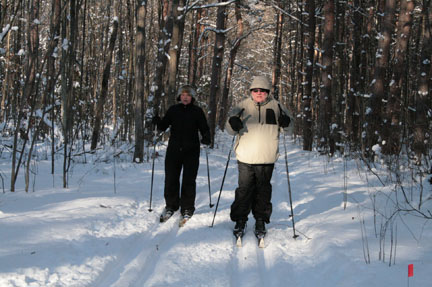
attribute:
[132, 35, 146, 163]
trunk — tall, high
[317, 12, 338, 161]
tree — tall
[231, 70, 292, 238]
person — skiing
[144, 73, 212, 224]
person — skiing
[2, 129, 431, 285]
snow — white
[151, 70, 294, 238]
people — skiing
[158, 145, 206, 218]
pants — black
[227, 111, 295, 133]
gloves — black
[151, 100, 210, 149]
jacket — black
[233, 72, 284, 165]
jacket — beige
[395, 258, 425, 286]
flag — red, small, trail marker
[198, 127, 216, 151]
glove — black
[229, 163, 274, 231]
pants — black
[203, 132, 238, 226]
ski poles — black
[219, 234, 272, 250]
skis — pair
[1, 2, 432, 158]
trees — bare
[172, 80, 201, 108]
hat — furry